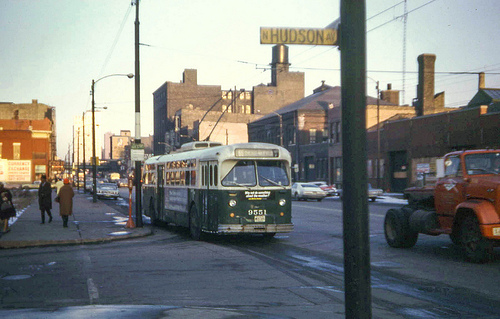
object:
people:
[36, 174, 54, 223]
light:
[124, 72, 135, 81]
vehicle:
[382, 146, 500, 264]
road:
[0, 178, 500, 318]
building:
[247, 53, 499, 196]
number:
[245, 208, 254, 218]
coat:
[37, 180, 54, 212]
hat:
[61, 175, 73, 185]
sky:
[0, 0, 500, 162]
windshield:
[223, 161, 257, 187]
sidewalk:
[0, 187, 155, 248]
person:
[57, 178, 76, 230]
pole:
[338, 0, 372, 319]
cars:
[292, 180, 326, 201]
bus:
[143, 138, 293, 241]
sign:
[259, 25, 338, 45]